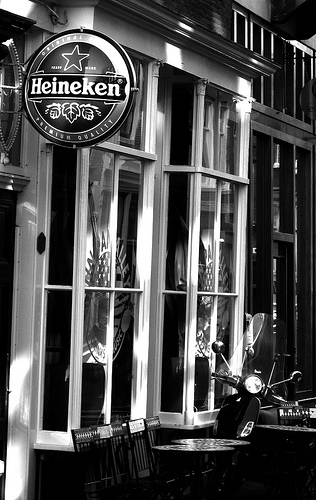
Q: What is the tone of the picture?
A: Black and white.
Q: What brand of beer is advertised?
A: Heineken.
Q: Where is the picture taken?
A: A cafe.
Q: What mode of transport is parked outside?
A: A motorcycle.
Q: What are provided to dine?
A: Table and chairs.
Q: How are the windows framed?
A: In wood.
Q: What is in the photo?
A: Black benches.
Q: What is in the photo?
A: Black moped.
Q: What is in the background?
A: Bay windows.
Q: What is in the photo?
A: Heineken logo.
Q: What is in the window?
A: A beer sign.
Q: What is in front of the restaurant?
A: A motorcycle.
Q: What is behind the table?
A: Chairs.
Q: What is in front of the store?
A: Table and chairs.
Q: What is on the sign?
A: Heineken.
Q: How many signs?
A: 1.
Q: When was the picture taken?
A: Daytime.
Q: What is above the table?
A: Windows.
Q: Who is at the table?
A: Nobody.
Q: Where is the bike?
A: Beside the table.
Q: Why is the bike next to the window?
A: Parked.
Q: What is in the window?
A: Labels.